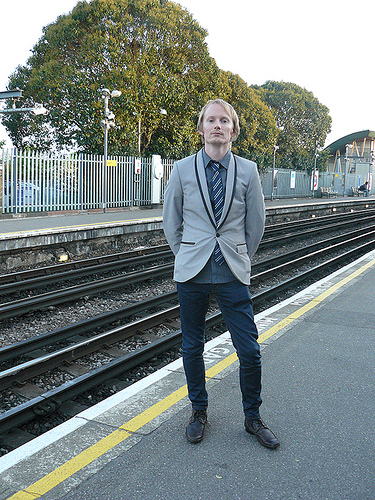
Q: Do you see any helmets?
A: No, there are no helmets.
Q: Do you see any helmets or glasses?
A: No, there are no helmets or glasses.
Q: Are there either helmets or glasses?
A: No, there are no helmets or glasses.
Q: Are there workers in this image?
A: No, there are no workers.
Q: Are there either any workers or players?
A: No, there are no workers or players.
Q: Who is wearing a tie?
A: The man is wearing a tie.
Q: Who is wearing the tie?
A: The man is wearing a tie.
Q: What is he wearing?
A: The man is wearing a tie.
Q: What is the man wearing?
A: The man is wearing a tie.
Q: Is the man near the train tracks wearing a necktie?
A: Yes, the man is wearing a necktie.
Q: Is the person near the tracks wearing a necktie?
A: Yes, the man is wearing a necktie.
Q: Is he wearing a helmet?
A: No, the man is wearing a necktie.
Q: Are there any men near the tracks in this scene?
A: Yes, there is a man near the tracks.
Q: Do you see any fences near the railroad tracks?
A: No, there is a man near the railroad tracks.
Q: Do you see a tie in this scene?
A: Yes, there is a tie.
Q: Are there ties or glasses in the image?
A: Yes, there is a tie.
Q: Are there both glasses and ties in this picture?
A: No, there is a tie but no glasses.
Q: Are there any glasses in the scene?
A: No, there are no glasses.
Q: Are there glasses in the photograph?
A: No, there are no glasses.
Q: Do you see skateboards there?
A: No, there are no skateboards.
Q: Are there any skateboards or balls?
A: No, there are no skateboards or balls.